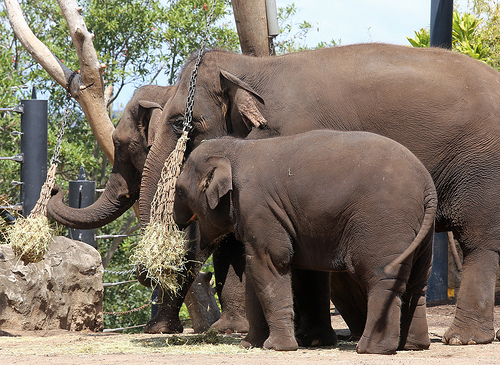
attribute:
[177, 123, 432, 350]
elephant — family, baby, brown, grey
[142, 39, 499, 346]
elephant — large, adult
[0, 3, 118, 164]
tree — green, tall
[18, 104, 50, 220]
fence post — metal, black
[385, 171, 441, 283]
tail — curved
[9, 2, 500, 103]
sky — blue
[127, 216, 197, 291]
hay — ball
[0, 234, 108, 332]
boulder — large, rock, giant, brown